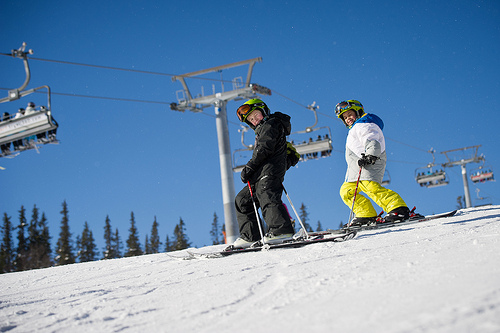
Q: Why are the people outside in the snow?
A: To ski.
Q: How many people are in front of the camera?
A: Two.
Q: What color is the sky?
A: Blue.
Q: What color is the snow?
A: White.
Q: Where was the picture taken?
A: On the ski slopes.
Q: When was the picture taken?
A: During the day.